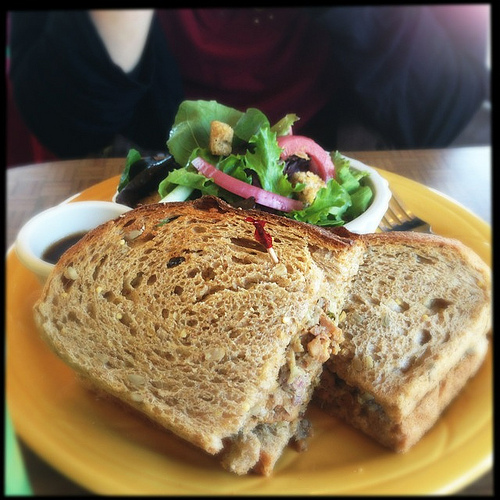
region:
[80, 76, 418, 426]
Food on the plate.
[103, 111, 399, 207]
Salad on the plate.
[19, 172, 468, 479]
Bread on the sandwich.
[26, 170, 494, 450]
Food on the yellow plate.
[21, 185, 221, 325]
Dressing in a dish.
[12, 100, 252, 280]
Yellow plate on the table.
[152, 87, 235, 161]
Crouton on the salad.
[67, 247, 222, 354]
Grains on the bread.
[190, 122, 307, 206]
Tomatoes on the salad.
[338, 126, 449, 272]
Fork on the plate.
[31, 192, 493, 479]
THE SANDWICH IS ON THE PLATE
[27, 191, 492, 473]
THE BREAD IS WHEAT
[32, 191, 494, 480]
THE SANDWICH IS CUT IN HALF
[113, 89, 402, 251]
THE SALAD IS ON THE PLATE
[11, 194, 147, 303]
THE SAUCE IS IN THE CUP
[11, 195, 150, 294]
THE SAUCE CUP IS WHITE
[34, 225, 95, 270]
THE SAUCE IS DARK BROWN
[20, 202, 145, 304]
THE SAUCE IS UNDER THE SANDWICH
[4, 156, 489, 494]
THE PLATE IS ROUND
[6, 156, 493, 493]
THE PLATE IS YELLOW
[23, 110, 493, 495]
A sandwich on a yellow plate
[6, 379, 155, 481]
A clean yellow plate beneath the sandwich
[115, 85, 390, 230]
A salad beside the sandwich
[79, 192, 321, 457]
Toasted slices of bread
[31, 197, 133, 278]
Dipping sauce in a bowl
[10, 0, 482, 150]
A person sitting at the table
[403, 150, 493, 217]
A wooden table beneath the food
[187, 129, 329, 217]
Onions in the salad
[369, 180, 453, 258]
A metal fork on the plate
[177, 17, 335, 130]
A red scarf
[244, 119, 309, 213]
this is green lettuce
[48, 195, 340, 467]
this is honey oat bread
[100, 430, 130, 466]
this is a yellow plate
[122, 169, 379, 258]
this is brown crust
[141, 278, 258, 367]
these are brown oats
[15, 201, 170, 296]
this is aujue sauce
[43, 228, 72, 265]
this is brown sauce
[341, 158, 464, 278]
this is a fork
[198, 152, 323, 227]
this is an onion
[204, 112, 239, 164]
this is a crouton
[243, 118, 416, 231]
salad in a bowl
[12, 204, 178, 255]
salad dressing in a small bowl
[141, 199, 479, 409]
sandwich is cut in half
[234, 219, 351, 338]
toothpick in sandwich to hold it together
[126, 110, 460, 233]
salad bowl is on the plate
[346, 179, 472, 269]
fork on the plate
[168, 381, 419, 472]
plate is a off yellow color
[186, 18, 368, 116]
woman's shirt is red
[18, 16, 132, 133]
woman's sweater is black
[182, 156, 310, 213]
red onion on the salad